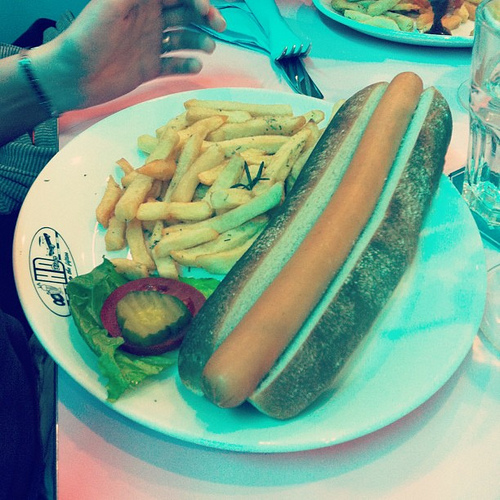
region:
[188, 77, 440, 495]
a hot dog on a bun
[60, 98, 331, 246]
french fries on a plate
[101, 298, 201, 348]
a sliced pickle on a plate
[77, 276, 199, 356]
a sliced tomato on a plate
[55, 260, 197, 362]
a piece of lettuce on a plate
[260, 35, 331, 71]
silver fork on a table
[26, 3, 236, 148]
a person's hand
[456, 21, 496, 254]
a clear water glass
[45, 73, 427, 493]
a cooked hot dog on a bun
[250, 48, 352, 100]
a silver butter knife on a table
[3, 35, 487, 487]
Person sitting in front of meal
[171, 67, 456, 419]
Large plain hot dog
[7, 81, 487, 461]
White plate holding hot dog and fries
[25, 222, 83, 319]
Logo on white plate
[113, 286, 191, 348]
Green and yellow pickle slice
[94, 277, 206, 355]
Pickle sitting on tomato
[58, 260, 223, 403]
Piece of green lettuce, tomato and pickle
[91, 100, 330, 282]
Lightly seasoned french fries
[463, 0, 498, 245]
Edge of water glass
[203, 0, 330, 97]
Fork and knife on table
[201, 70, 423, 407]
very long hot dog inside a near burnt bun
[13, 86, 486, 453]
plate of food including hot dog and fries found on a table top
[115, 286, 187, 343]
single slice of dill pickle served with a meal as a garnish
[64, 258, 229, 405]
slice of lettuce being served with a hot dog and fries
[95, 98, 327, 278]
pile of seasoned fries served with a hot dog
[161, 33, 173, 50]
wedding band found on the hand of a person seated at the table ready to eat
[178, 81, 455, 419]
hot dog bun that looks almost burnt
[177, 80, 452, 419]
near burnt hot dog bun holding a hot dog and ready to eat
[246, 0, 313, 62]
fork on top of a butter knife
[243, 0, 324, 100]
butter knife on a table near a plate of food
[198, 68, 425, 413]
tubular red hot dog on bun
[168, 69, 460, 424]
long brown bun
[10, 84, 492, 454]
circular white dish on white table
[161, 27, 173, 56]
silver metal ring on hand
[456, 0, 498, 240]
clear drinking glass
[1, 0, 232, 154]
hand of person above table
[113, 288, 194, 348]
flat circular pickle slice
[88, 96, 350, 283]
light yellow and light brown french fries on white plate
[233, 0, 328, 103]
silver metal silverware on white table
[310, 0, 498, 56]
circular white plate on white table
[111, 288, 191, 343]
pickle on a plate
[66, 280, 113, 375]
lettuce on a plate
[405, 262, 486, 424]
white plate where food is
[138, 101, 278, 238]
french fries on a plate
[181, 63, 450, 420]
hotdog in a bun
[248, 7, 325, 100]
utensils on a table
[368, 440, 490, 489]
white tablecloth on a table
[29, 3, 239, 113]
hand of a man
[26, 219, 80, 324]
design on a plate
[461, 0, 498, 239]
glass on a table